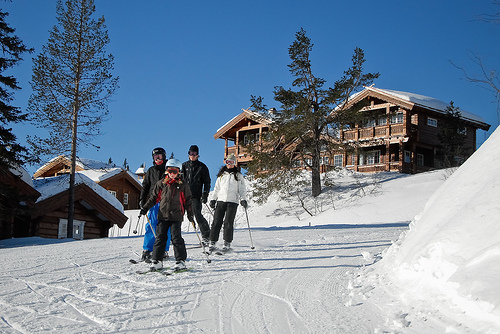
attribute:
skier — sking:
[214, 150, 249, 258]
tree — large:
[244, 33, 368, 197]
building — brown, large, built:
[217, 91, 486, 181]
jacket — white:
[211, 171, 246, 204]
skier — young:
[138, 148, 172, 259]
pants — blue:
[147, 202, 171, 252]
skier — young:
[150, 156, 192, 273]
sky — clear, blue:
[4, 1, 500, 187]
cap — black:
[189, 143, 200, 155]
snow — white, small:
[313, 182, 428, 286]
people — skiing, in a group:
[117, 103, 279, 288]